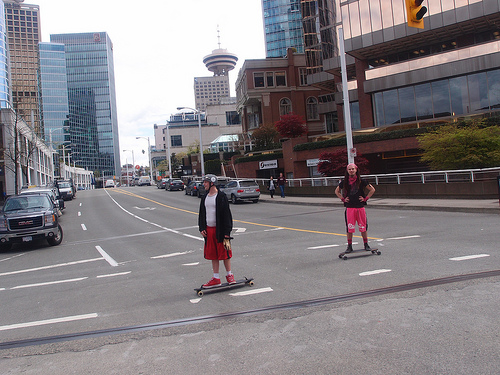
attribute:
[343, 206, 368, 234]
shorts — pink, black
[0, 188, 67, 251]
car — parked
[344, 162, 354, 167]
bandana — pink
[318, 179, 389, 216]
shirt — black, cotton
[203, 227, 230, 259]
shorts — red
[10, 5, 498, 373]
day — photo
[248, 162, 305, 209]
people — walking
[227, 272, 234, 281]
shoe — red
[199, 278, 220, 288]
shoe — red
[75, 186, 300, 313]
paved street — gray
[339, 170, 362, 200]
hair — long, twisted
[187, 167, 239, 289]
skateboarder — male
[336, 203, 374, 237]
shorts — pink, black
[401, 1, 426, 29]
traffic light — yellow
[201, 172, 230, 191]
helmet — black, white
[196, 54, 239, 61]
ring — dark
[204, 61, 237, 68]
ring — dark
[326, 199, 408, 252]
shorts — pink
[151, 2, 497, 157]
buildings — tall, short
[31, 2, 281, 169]
sky — bright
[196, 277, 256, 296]
skateboard — long board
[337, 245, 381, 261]
skateboard — long board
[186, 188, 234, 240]
tee shirt — white, cotton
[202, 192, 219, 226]
tank top — white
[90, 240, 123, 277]
line — white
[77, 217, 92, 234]
line — white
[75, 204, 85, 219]
line — white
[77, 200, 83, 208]
line — white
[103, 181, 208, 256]
line — white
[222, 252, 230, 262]
stripe — black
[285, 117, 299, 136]
leaves — red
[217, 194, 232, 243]
jacket — black, sweatshirt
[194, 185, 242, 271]
clothes — baggy